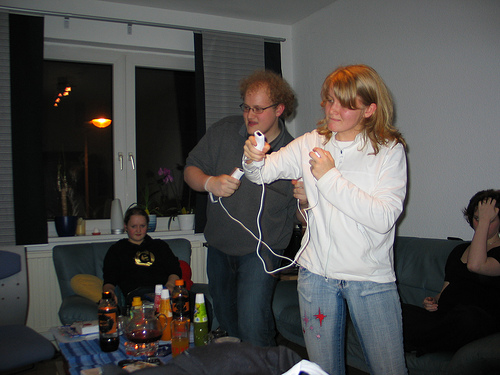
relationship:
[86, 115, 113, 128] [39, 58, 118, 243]
light in window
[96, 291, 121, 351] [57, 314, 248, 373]
bottle on top of table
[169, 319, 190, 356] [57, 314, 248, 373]
glass on top of table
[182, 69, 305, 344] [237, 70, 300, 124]
man with hair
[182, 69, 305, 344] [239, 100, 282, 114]
man with glasses.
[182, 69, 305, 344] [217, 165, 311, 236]
man holding wii controller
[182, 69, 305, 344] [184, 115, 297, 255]
man wearing shirt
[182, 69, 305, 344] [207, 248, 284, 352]
man wearing jeans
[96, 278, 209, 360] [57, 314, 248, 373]
drinks are on top of table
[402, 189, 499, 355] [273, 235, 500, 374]
girl on top of sofa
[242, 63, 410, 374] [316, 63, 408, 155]
girl with hair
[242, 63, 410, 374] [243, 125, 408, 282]
person wearing jacket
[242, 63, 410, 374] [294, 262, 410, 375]
person wearing jeans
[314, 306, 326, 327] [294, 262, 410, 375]
red star on top of jeans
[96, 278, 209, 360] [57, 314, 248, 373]
drinks are on top of table.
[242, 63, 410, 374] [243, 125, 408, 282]
person in sweat shirt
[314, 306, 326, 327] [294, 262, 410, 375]
red star on jeans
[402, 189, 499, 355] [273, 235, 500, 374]
girl on sofa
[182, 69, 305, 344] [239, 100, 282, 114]
man wearing glasses